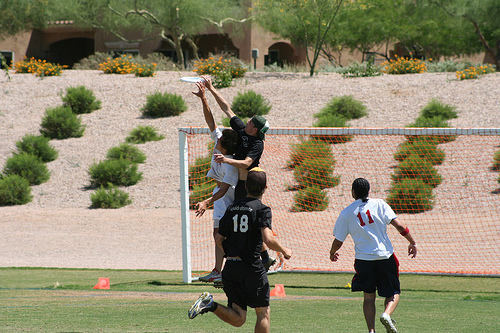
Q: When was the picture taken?
A: Daytime.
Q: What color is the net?
A: White.